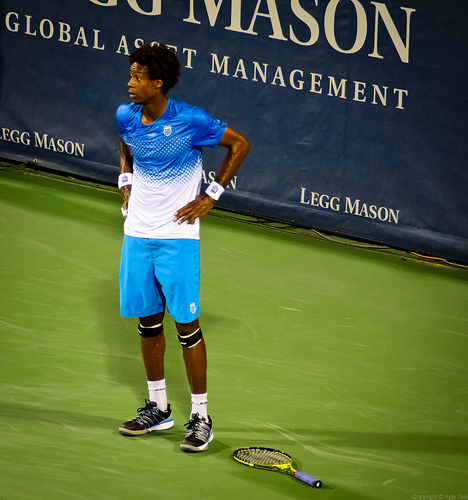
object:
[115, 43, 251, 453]
man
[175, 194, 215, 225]
hand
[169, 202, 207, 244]
hip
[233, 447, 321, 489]
racket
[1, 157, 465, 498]
court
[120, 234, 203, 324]
shorts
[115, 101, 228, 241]
shirt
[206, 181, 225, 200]
wristband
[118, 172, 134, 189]
wristband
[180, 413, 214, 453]
shoe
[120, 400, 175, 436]
shoe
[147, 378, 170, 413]
sock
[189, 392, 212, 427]
sock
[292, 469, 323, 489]
handle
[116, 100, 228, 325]
outfit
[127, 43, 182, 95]
hair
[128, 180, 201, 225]
waist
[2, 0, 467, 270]
advertisement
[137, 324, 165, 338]
knee band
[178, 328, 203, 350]
knee band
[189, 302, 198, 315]
logo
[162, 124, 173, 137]
logo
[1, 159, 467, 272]
edge